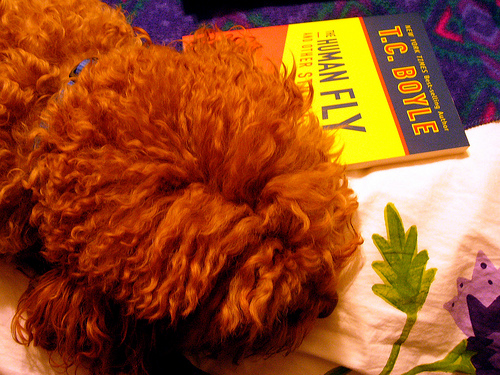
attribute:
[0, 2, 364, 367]
dog — sleeping, hairy, cute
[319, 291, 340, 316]
nose — black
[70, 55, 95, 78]
collar — stitched, blue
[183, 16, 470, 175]
book — yellow, blue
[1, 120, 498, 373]
sheet — beige, white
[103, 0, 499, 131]
shawl — embroidered, purple, pink, blue, green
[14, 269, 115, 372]
ear — brown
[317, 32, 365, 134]
title — the human fly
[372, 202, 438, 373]
leaf — appliqued, printed, green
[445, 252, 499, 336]
flower — appliqued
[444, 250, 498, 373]
flower — purple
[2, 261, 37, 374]
part — white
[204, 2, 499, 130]
pattern — purple diamond